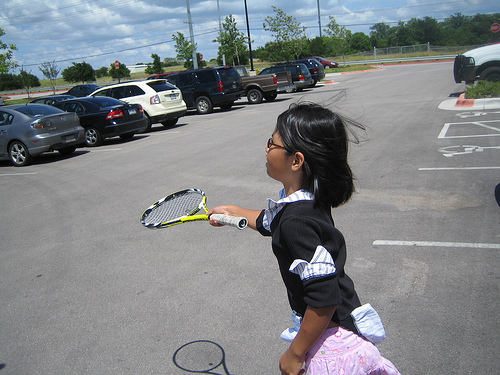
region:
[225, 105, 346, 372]
this is a girl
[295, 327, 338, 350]
the girl is light skinned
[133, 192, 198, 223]
this is a racket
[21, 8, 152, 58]
this is the sky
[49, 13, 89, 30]
these are the clouds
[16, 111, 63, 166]
this is a car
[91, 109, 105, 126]
the car is black in color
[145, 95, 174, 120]
the car is white in color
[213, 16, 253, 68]
this is a tree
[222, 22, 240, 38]
the leaves are green in color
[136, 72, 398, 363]
A young girl holding a tennis racket.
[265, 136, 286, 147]
A pair of glasses.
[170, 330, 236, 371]
A shadow on the ground of a tennis racket.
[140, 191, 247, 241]
A black and yellow tennis racket with a white handle.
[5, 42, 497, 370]
A parking lot.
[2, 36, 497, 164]
Parked vehicles.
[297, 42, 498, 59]
A grey chain linked fence.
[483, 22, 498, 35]
A red and white stop sign.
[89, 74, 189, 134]
A white SUV.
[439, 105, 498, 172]
Handicapped parking spaces.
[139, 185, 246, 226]
a white, black, and yellow tennis racquet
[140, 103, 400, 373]
a young girl holding a tennis racquet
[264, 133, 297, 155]
a pair of glasses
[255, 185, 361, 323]
a black long sleeve shirt with white and blue plaid under shirt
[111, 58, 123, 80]
a red and white street sign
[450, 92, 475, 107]
red painting on edge of rounded curb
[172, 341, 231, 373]
shadow of a tennis racquet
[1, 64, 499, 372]
a parking lot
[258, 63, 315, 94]
a small dark car with silver bumper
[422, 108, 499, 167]
handicap parking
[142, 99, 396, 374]
a small child holding a tennis racquet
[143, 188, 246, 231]
a black and yellow tennis racquet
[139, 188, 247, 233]
tennis racquet with white handle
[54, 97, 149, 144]
a black round body sedan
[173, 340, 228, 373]
a shadow of a tennis racquet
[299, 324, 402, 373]
a pink design skirt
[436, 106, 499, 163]
paintings showing handicap parking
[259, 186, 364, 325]
a black and white long sleeve shirt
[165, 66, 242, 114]
a dark color SUV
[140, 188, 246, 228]
a yellow and black tennis racquet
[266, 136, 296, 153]
a pair of corrective glasses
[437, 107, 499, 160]
handicap parkying symbols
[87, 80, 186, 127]
a white SUV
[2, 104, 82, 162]
a smoke grey four door car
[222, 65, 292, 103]
a copper color pickup truck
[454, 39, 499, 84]
front of a large whtie truck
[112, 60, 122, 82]
a red and whtie sstreet sign